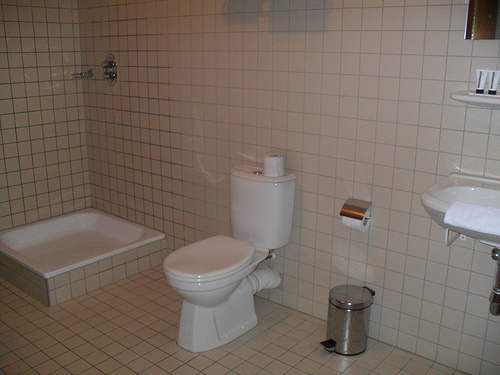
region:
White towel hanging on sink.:
[441, 198, 498, 235]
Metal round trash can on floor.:
[319, 270, 376, 365]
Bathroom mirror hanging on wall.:
[462, 3, 497, 43]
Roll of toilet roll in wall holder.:
[337, 195, 372, 231]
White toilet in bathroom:
[161, 148, 293, 354]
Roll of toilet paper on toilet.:
[262, 153, 284, 180]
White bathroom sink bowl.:
[419, 163, 499, 316]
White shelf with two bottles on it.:
[452, 63, 498, 114]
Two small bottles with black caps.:
[470, 58, 497, 95]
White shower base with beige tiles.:
[0, 199, 172, 309]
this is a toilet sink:
[162, 220, 260, 347]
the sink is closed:
[164, 237, 256, 349]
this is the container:
[225, 187, 282, 228]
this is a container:
[319, 277, 374, 358]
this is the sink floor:
[17, 208, 129, 277]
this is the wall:
[187, 10, 291, 116]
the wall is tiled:
[151, 14, 348, 116]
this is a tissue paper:
[262, 150, 285, 177]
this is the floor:
[82, 310, 157, 372]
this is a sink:
[434, 183, 489, 213]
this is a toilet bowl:
[158, 241, 268, 338]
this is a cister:
[218, 150, 303, 252]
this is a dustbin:
[318, 274, 374, 366]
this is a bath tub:
[8, 214, 163, 296]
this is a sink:
[429, 169, 498, 254]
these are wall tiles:
[246, 84, 282, 121]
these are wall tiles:
[126, 105, 164, 164]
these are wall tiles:
[299, 135, 356, 192]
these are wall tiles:
[143, 90, 178, 137]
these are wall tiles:
[121, 172, 166, 206]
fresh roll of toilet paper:
[262, 152, 285, 178]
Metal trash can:
[316, 285, 376, 354]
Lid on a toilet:
[160, 236, 255, 280]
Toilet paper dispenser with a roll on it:
[337, 197, 373, 232]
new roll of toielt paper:
[261, 153, 286, 179]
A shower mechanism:
[97, 53, 120, 88]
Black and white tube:
[474, 68, 489, 94]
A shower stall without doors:
[3, 203, 168, 305]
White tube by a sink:
[471, 67, 489, 92]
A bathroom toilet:
[162, 166, 297, 352]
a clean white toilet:
[158, 161, 305, 346]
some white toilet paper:
[262, 145, 292, 179]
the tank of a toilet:
[230, 165, 295, 247]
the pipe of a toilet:
[251, 259, 286, 295]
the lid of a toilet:
[173, 228, 246, 278]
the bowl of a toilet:
[171, 280, 244, 312]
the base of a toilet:
[172, 304, 255, 344]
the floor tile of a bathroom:
[65, 305, 131, 352]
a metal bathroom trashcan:
[323, 282, 372, 359]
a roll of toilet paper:
[334, 193, 372, 233]